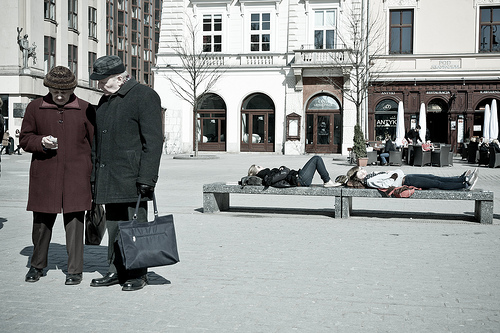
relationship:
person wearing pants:
[18, 65, 96, 285] [27, 209, 89, 271]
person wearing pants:
[18, 65, 96, 285] [29, 205, 94, 282]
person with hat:
[18, 66, 95, 283] [39, 64, 78, 89]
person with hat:
[87, 56, 165, 289] [86, 52, 124, 79]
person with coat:
[87, 56, 165, 289] [93, 75, 163, 205]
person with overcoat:
[18, 66, 95, 283] [20, 91, 96, 215]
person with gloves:
[87, 56, 165, 289] [136, 183, 157, 201]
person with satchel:
[87, 56, 165, 289] [116, 187, 180, 272]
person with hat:
[18, 65, 96, 285] [28, 52, 90, 95]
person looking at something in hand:
[18, 65, 96, 285] [29, 125, 68, 155]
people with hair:
[335, 165, 480, 188] [347, 170, 369, 188]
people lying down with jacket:
[335, 165, 480, 188] [362, 168, 404, 190]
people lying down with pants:
[335, 165, 480, 188] [402, 173, 465, 191]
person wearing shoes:
[87, 56, 165, 292] [93, 259, 165, 296]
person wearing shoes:
[18, 65, 96, 285] [24, 265, 83, 285]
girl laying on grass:
[248, 156, 344, 188] [223, 176, 486, 197]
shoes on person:
[26, 262, 51, 282] [87, 55, 156, 267]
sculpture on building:
[15, 20, 41, 72] [4, 0, 159, 145]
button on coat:
[99, 127, 109, 134] [93, 75, 163, 205]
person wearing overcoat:
[18, 65, 96, 285] [20, 91, 96, 215]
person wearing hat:
[18, 65, 96, 285] [41, 65, 77, 92]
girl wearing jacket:
[246, 155, 341, 187] [258, 167, 300, 187]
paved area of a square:
[14, 157, 499, 330] [237, 210, 457, 333]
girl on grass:
[248, 156, 344, 188] [230, 176, 488, 222]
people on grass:
[335, 165, 480, 188] [204, 174, 499, 234]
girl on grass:
[248, 156, 344, 188] [204, 174, 499, 234]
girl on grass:
[248, 156, 344, 188] [190, 165, 496, 228]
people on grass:
[347, 169, 477, 189] [196, 169, 494, 224]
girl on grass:
[248, 156, 344, 188] [196, 169, 494, 224]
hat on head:
[79, 53, 129, 79] [76, 50, 145, 95]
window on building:
[386, 6, 415, 56] [359, 0, 493, 183]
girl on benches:
[248, 156, 344, 188] [202, 175, 499, 230]